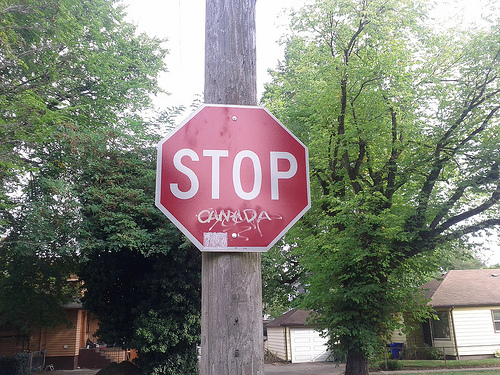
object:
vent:
[63, 345, 67, 349]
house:
[0, 258, 136, 371]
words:
[194, 205, 283, 233]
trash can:
[390, 342, 404, 358]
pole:
[203, 0, 255, 105]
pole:
[200, 251, 262, 373]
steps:
[78, 347, 125, 367]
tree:
[0, 0, 159, 372]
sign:
[151, 102, 311, 259]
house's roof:
[402, 267, 500, 306]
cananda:
[194, 205, 272, 227]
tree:
[262, 6, 499, 374]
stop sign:
[154, 101, 312, 252]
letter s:
[167, 144, 201, 204]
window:
[488, 308, 500, 336]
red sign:
[156, 98, 311, 256]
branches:
[256, 2, 499, 374]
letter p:
[269, 150, 299, 200]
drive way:
[262, 363, 352, 373]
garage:
[266, 307, 345, 363]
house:
[267, 264, 499, 359]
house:
[380, 269, 498, 361]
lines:
[229, 311, 258, 361]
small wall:
[72, 340, 136, 366]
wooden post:
[189, 8, 280, 362]